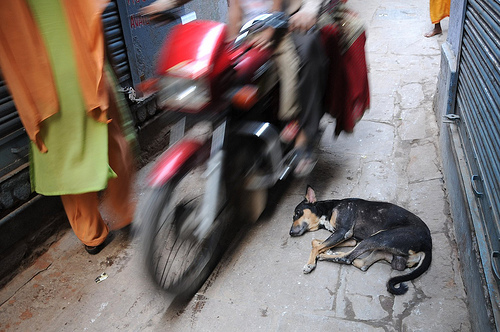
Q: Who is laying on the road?
A: A dog.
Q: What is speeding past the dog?
A: A motorcycle.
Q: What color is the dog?
A: Black and brown.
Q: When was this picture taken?
A: Daytime.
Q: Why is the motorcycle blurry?
A: It is in motion.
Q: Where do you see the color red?
A: On the motorcycle.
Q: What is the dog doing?
A: Laying down.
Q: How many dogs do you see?
A: 1.